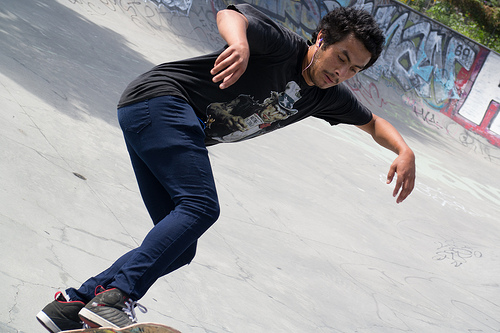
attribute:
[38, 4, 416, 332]
man — skateboarding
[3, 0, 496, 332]
pavement — gray, large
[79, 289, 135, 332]
shoe — black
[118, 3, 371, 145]
shirt — black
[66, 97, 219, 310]
jeans — skinny, blue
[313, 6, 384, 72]
hair — curly, black